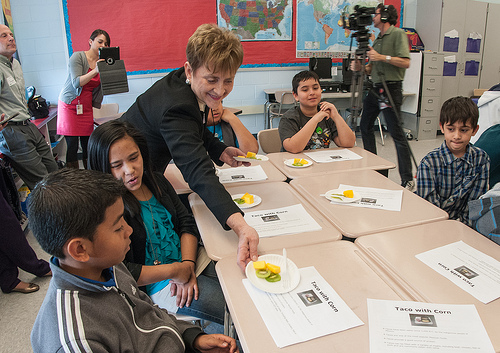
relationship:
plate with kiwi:
[245, 258, 302, 287] [255, 269, 271, 280]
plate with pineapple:
[245, 258, 302, 287] [253, 261, 267, 270]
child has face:
[418, 95, 490, 228] [446, 122, 473, 147]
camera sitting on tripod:
[340, 3, 375, 31] [344, 30, 419, 171]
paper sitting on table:
[414, 239, 499, 305] [354, 218, 499, 352]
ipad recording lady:
[97, 46, 120, 66] [119, 22, 259, 278]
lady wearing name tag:
[56, 28, 111, 169] [75, 98, 83, 115]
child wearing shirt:
[418, 95, 490, 228] [416, 139, 490, 227]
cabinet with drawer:
[402, 49, 446, 141] [422, 53, 446, 77]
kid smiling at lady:
[278, 70, 356, 155] [119, 22, 259, 278]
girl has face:
[87, 119, 225, 327] [108, 148, 141, 190]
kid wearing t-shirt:
[278, 70, 356, 155] [277, 105, 339, 151]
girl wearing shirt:
[87, 119, 225, 327] [138, 193, 182, 296]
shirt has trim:
[138, 193, 182, 296] [144, 200, 182, 263]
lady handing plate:
[119, 22, 259, 278] [245, 258, 302, 287]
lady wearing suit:
[119, 22, 259, 278] [119, 67, 244, 231]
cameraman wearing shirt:
[350, 3, 414, 188] [369, 24, 411, 83]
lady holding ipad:
[56, 28, 111, 169] [97, 46, 120, 66]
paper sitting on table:
[241, 265, 364, 349] [214, 239, 417, 352]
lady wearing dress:
[56, 28, 111, 169] [56, 66, 101, 137]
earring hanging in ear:
[185, 78, 192, 84] [183, 60, 193, 84]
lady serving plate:
[119, 22, 259, 278] [245, 258, 302, 287]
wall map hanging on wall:
[215, 2, 293, 42] [0, 1, 402, 161]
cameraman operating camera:
[350, 3, 414, 188] [340, 3, 375, 31]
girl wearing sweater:
[87, 119, 225, 327] [123, 171, 201, 295]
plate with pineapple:
[325, 188, 361, 207] [344, 190, 355, 200]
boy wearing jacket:
[26, 165, 241, 353] [30, 254, 209, 352]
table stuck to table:
[354, 218, 499, 352] [214, 239, 417, 352]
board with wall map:
[60, 1, 405, 80] [215, 2, 293, 42]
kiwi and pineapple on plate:
[261, 259, 279, 277] [245, 258, 302, 287]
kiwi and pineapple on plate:
[325, 190, 354, 205] [325, 188, 361, 207]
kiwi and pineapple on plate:
[237, 195, 253, 204] [230, 194, 259, 207]